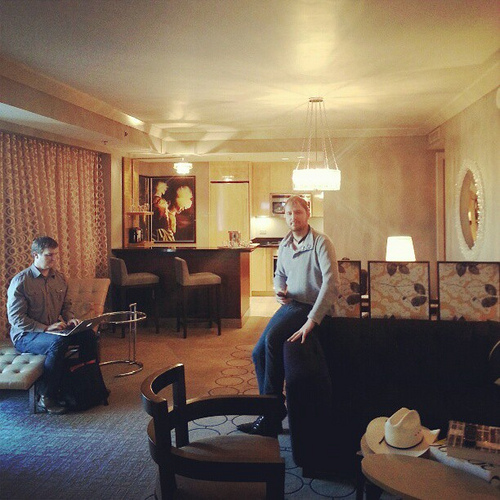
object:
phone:
[272, 283, 339, 321]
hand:
[261, 279, 328, 329]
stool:
[121, 244, 259, 328]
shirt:
[7, 270, 78, 329]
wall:
[440, 87, 499, 179]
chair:
[133, 363, 285, 494]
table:
[96, 303, 146, 378]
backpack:
[58, 341, 115, 411]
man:
[7, 235, 100, 415]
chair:
[1, 277, 108, 412]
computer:
[47, 313, 109, 337]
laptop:
[45, 312, 112, 337]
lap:
[24, 325, 95, 339]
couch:
[289, 311, 499, 480]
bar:
[109, 240, 256, 329]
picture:
[135, 175, 196, 247]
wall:
[119, 130, 431, 292]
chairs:
[110, 254, 229, 340]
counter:
[104, 240, 256, 311]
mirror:
[441, 154, 472, 255]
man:
[232, 182, 362, 439]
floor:
[16, 287, 496, 500]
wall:
[436, 162, 496, 273]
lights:
[290, 93, 356, 204]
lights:
[160, 134, 198, 190]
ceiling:
[2, 3, 498, 139]